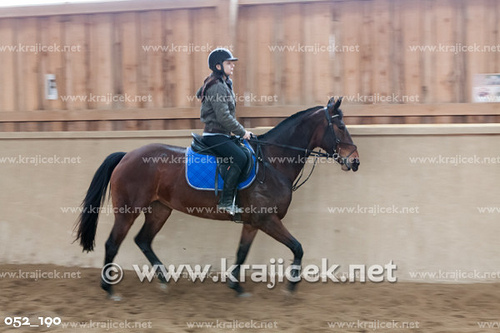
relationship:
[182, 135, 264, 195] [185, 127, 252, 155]
pad under saddle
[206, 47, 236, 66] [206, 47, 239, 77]
helmet on head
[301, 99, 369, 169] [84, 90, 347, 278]
head of horse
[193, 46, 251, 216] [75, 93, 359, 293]
person on top of horse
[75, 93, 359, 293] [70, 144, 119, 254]
horse has tail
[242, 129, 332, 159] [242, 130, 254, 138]
horse reign in hand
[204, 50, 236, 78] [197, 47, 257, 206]
head of person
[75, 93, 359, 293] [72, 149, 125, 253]
horse has tail